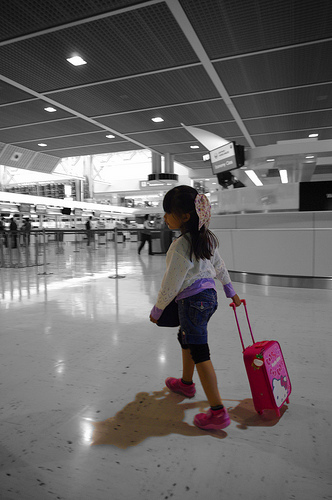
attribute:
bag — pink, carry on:
[237, 337, 296, 418]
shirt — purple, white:
[151, 230, 235, 316]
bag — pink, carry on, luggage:
[227, 298, 313, 425]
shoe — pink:
[163, 372, 195, 398]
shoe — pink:
[189, 407, 228, 432]